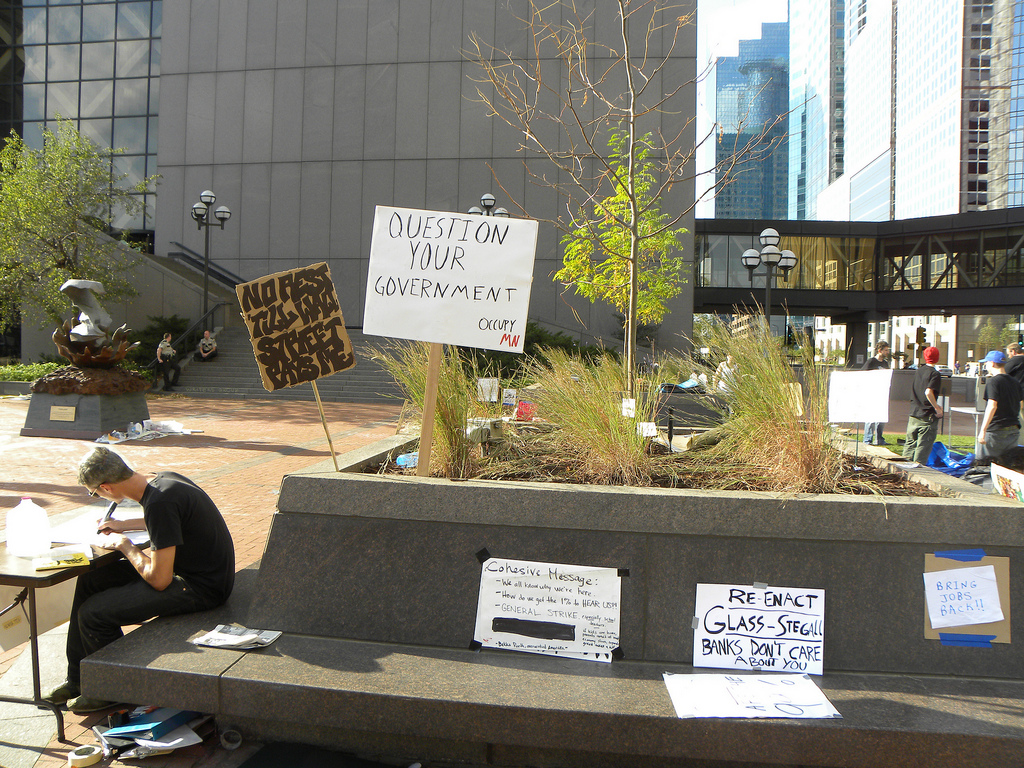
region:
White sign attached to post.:
[357, 189, 514, 465]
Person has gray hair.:
[56, 443, 146, 486]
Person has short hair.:
[73, 451, 137, 489]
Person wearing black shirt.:
[138, 480, 252, 605]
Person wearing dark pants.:
[54, 553, 185, 656]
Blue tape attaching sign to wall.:
[931, 527, 1001, 651]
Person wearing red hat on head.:
[913, 350, 945, 364]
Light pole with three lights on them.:
[178, 180, 233, 320]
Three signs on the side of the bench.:
[471, 546, 895, 742]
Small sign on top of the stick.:
[362, 174, 522, 440]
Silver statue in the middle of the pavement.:
[38, 253, 169, 422]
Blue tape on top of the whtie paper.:
[921, 546, 988, 566]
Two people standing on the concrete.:
[904, 335, 1015, 504]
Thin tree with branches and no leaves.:
[465, 7, 731, 501]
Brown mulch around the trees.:
[848, 452, 929, 525]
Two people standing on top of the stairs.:
[149, 315, 227, 399]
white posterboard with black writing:
[351, 203, 539, 360]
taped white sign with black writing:
[686, 571, 830, 676]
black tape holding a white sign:
[465, 541, 636, 665]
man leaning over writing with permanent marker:
[42, 440, 238, 715]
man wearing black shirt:
[46, 442, 237, 717]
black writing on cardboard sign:
[232, 255, 357, 396]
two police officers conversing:
[153, 323, 224, 390]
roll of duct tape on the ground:
[65, 736, 104, 766]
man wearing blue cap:
[969, 344, 1018, 458]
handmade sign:
[356, 187, 549, 365]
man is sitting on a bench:
[51, 434, 255, 695]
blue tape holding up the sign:
[928, 540, 1008, 570]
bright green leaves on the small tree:
[535, 120, 710, 336]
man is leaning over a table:
[7, 447, 251, 736]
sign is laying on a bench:
[655, 642, 853, 738]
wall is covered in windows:
[2, 3, 173, 267]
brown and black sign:
[241, 259, 362, 395]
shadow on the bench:
[289, 621, 400, 678]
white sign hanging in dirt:
[366, 195, 534, 366]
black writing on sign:
[375, 205, 512, 322]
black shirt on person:
[133, 470, 257, 619]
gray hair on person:
[65, 448, 138, 491]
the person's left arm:
[104, 494, 181, 590]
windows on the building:
[10, 8, 167, 243]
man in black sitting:
[72, 448, 240, 651]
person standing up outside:
[900, 341, 957, 453]